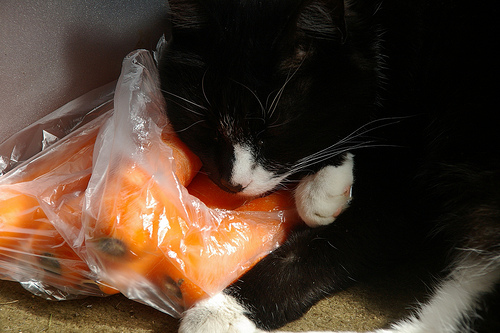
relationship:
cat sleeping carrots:
[154, 12, 498, 332] [20, 109, 272, 304]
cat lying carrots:
[151, 0, 499, 333] [68, 151, 288, 295]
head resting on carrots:
[159, 0, 391, 196] [4, 106, 254, 299]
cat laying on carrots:
[151, 0, 499, 333] [2, 59, 300, 319]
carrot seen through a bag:
[94, 120, 199, 263] [81, 52, 288, 325]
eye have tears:
[257, 110, 303, 130] [255, 137, 267, 146]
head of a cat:
[154, 7, 391, 193] [154, 12, 498, 332]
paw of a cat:
[295, 164, 354, 229] [154, 12, 498, 332]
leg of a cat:
[180, 216, 384, 331] [154, 12, 498, 332]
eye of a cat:
[252, 111, 307, 155] [154, 12, 498, 332]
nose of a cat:
[220, 172, 253, 193] [83, 9, 499, 324]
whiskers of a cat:
[283, 123, 389, 176] [129, 3, 497, 328]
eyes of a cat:
[170, 104, 305, 151] [154, 12, 498, 332]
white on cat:
[229, 142, 291, 198] [154, 12, 498, 332]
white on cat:
[294, 152, 356, 228] [154, 12, 498, 332]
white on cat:
[172, 291, 268, 332] [154, 12, 498, 332]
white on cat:
[368, 247, 497, 332] [154, 12, 498, 332]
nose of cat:
[173, 130, 270, 212] [154, 12, 498, 332]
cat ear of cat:
[296, 0, 343, 39] [154, 12, 498, 332]